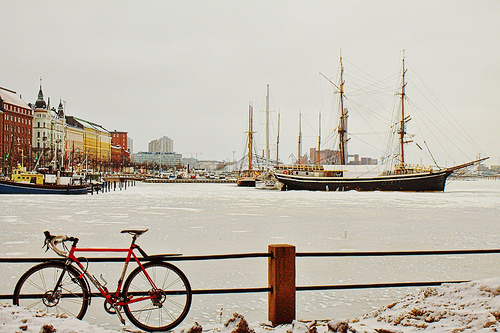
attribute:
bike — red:
[14, 230, 189, 331]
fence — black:
[1, 243, 493, 315]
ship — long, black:
[275, 41, 492, 192]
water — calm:
[2, 177, 498, 328]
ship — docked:
[1, 126, 108, 198]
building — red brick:
[1, 86, 33, 171]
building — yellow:
[83, 114, 113, 168]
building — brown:
[69, 115, 86, 162]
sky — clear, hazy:
[3, 4, 499, 157]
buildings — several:
[1, 95, 131, 182]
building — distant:
[134, 126, 185, 167]